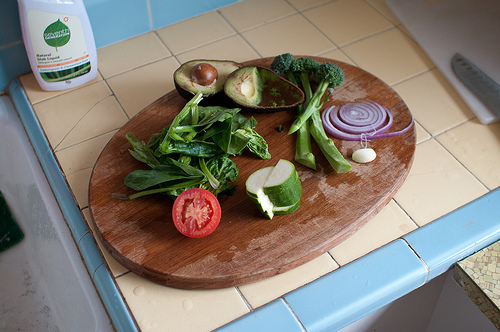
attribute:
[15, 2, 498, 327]
counter — blue, white, tiled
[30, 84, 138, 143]
tiles — tan, blue, ceramic